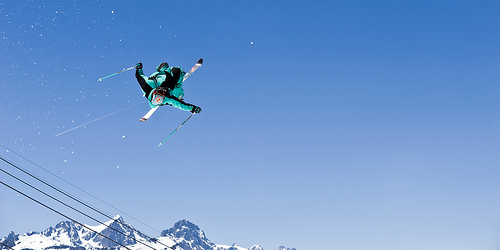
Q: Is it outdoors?
A: Yes, it is outdoors.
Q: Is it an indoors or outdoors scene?
A: It is outdoors.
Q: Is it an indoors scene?
A: No, it is outdoors.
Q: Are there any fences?
A: No, there are no fences.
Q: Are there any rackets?
A: No, there are no rackets.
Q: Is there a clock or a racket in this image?
A: No, there are no rackets or clocks.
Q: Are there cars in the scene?
A: No, there are no cars.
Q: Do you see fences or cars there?
A: No, there are no cars or fences.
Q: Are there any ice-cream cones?
A: No, there are no ice-cream cones.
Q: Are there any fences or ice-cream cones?
A: No, there are no ice-cream cones or fences.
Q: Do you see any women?
A: No, there are no women.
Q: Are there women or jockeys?
A: No, there are no women or jockeys.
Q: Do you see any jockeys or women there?
A: No, there are no women or jockeys.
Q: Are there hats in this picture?
A: Yes, there is a hat.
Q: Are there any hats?
A: Yes, there is a hat.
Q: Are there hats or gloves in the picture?
A: Yes, there is a hat.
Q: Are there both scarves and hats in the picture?
A: No, there is a hat but no scarves.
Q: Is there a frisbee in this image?
A: No, there are no frisbees.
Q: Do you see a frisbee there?
A: No, there are no frisbees.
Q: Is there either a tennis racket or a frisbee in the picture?
A: No, there are no frisbees or rackets.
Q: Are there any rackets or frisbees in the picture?
A: No, there are no frisbees or rackets.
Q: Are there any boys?
A: No, there are no boys.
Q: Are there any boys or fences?
A: No, there are no boys or fences.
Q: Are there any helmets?
A: Yes, there is a helmet.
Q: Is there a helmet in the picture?
A: Yes, there is a helmet.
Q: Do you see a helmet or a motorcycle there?
A: Yes, there is a helmet.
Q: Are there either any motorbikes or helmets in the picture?
A: Yes, there is a helmet.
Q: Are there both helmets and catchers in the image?
A: No, there is a helmet but no catchers.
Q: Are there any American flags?
A: No, there are no American flags.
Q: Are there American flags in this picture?
A: No, there are no American flags.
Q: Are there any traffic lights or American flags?
A: No, there are no American flags or traffic lights.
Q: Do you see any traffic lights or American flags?
A: No, there are no American flags or traffic lights.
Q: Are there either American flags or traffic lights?
A: No, there are no American flags or traffic lights.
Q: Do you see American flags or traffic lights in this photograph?
A: No, there are no American flags or traffic lights.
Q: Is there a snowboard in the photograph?
A: No, there are no snowboards.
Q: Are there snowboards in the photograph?
A: No, there are no snowboards.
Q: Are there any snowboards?
A: No, there are no snowboards.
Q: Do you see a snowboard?
A: No, there are no snowboards.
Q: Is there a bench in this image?
A: No, there are no benches.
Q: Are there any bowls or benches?
A: No, there are no benches or bowls.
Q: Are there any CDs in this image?
A: No, there are no cds.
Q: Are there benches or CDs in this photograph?
A: No, there are no CDs or benches.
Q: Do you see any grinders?
A: No, there are no grinders.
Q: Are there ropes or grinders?
A: No, there are no grinders or ropes.